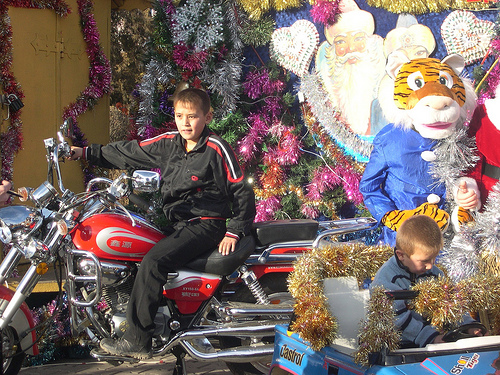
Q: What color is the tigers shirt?
A: Blue.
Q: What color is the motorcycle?
A: Red.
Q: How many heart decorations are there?
A: 2.